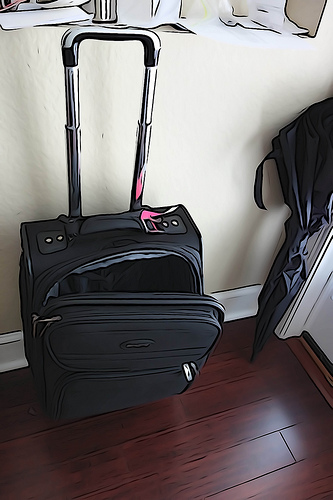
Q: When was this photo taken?
A: During the day.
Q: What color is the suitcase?
A: Black.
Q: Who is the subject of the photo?
A: The case.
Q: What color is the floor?
A: Brown.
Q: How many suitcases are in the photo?
A: One.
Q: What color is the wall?
A: White.